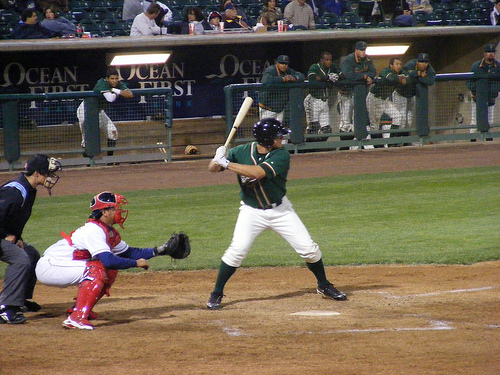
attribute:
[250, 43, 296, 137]
player — baseball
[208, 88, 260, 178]
baseball bat — tan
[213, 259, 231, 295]
sock — green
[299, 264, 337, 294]
sock — green